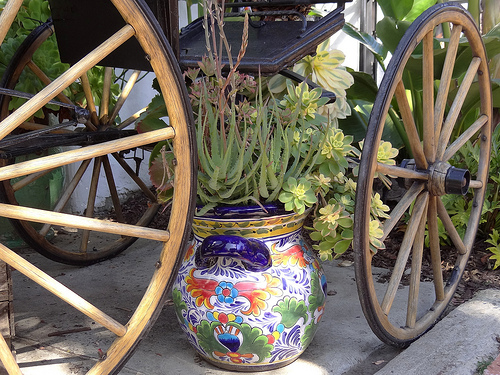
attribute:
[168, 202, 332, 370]
pot — colorful, ceramic, light, green, multi colored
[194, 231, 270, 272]
handle — blue, dark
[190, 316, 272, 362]
flower decorations — green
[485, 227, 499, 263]
leaves — green, yellow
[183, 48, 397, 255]
plant — aloe, green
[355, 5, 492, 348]
wheel — wooden, large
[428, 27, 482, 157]
spokes — wood, large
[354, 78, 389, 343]
tire — rubber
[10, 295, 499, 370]
floor — cement, gray, paved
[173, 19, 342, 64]
seat — antique, black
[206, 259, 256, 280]
flower decorations — blue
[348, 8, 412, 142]
leaves — large, green, big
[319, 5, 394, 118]
wall — painted, white